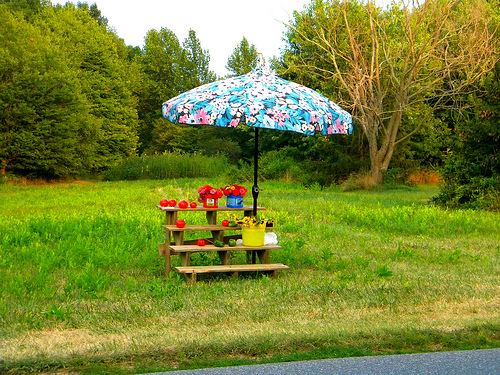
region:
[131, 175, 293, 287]
vegetable stand in the grass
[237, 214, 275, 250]
bucket of flowers on a stand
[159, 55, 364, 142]
umbrella on a pole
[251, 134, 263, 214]
pole of an umbrella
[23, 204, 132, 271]
green grass in a field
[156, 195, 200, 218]
tomatoes on a stand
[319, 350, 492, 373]
street next to a field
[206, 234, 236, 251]
cucumbers on a stand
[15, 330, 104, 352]
brown patch of grass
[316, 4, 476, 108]
bare tree in a field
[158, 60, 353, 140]
an open umbrella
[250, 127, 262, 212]
the pole of the umbrella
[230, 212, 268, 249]
flowers in a yellow bucket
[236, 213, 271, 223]
yellow sunflowers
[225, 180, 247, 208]
red flowers in a blue bucket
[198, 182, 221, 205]
red flowers in a red bucket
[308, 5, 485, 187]
a tree with no leaves on it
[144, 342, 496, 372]
road in front of the grass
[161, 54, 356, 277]
an umbrella stand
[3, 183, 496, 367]
a grassy field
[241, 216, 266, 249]
a yellow bucket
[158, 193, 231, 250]
tomatoes on steps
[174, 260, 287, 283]
the first step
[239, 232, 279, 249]
a white bag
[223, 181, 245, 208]
a blue kettle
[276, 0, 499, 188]
a tree with no leaves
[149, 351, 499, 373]
a pave street beside the grass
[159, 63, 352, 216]
Bright blue and pink floral umbrella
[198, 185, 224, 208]
Red bucket of flowers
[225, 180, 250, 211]
Blue bucket of flowers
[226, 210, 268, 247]
Yellow bucket of flowers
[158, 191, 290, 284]
Wooden steps under umbrella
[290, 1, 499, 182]
One tree without green leaves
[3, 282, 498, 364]
Strip of brown, dry grass by road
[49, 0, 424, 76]
Bright light gray sky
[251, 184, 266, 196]
Crank on umbrella shaft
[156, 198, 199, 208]
red flowers in a row on the top step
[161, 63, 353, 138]
Flower pattern on an umbrella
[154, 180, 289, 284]
Wood steps with flowers and fruit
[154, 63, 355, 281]
Stand under an umbrella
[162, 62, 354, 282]
Flower patio umbrella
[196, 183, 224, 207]
Red container with red flowers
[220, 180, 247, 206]
Red flowers in a blue container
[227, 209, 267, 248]
Sunflowers in a yellow bucket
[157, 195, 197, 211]
Four red apples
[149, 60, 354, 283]
Small stand and umbrella in a park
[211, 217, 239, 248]
Three green peppers